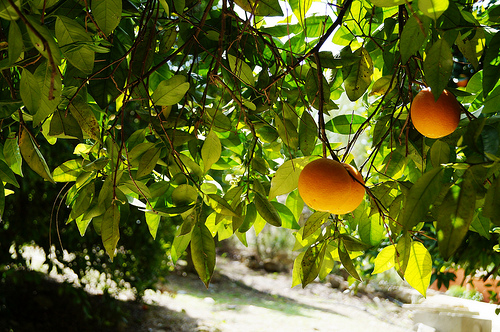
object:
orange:
[298, 154, 365, 214]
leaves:
[391, 229, 410, 282]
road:
[10, 224, 404, 331]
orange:
[407, 85, 465, 140]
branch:
[121, 135, 160, 214]